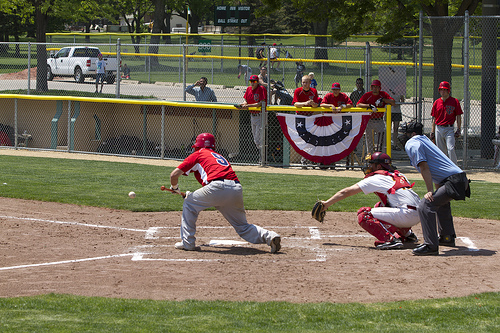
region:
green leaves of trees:
[0, 1, 482, 31]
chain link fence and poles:
[2, 11, 498, 167]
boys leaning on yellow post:
[240, 71, 390, 111]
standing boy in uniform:
[428, 78, 464, 155]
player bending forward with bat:
[163, 132, 285, 251]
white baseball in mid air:
[123, 187, 143, 204]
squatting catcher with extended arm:
[310, 151, 415, 248]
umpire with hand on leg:
[397, 120, 468, 257]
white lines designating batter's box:
[129, 222, 328, 262]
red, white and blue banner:
[276, 109, 375, 166]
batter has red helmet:
[190, 119, 210, 154]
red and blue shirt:
[183, 144, 250, 186]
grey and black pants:
[172, 181, 274, 241]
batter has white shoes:
[252, 222, 277, 263]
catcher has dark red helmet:
[355, 147, 396, 173]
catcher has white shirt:
[337, 177, 452, 223]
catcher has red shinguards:
[357, 205, 422, 255]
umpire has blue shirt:
[401, 130, 468, 192]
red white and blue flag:
[281, 110, 378, 170]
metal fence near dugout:
[15, 32, 335, 177]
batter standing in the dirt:
[133, 123, 296, 258]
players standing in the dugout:
[234, 67, 404, 171]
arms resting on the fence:
[289, 93, 316, 113]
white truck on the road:
[30, 41, 130, 85]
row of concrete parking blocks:
[117, 73, 232, 92]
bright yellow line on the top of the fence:
[3, 86, 394, 131]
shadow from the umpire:
[444, 239, 490, 259]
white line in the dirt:
[3, 241, 131, 278]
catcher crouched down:
[307, 141, 421, 258]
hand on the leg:
[422, 186, 436, 203]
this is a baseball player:
[161, 125, 262, 255]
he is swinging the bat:
[156, 127, 249, 250]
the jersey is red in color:
[186, 147, 231, 182]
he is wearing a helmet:
[193, 132, 215, 146]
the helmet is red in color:
[195, 135, 213, 146]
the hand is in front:
[310, 182, 357, 224]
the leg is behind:
[231, 210, 285, 254]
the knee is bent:
[228, 216, 260, 240]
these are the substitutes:
[294, 73, 391, 108]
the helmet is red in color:
[434, 79, 451, 88]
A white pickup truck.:
[42, 45, 122, 80]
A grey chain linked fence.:
[0, 10, 497, 171]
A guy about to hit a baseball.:
[125, 130, 280, 255]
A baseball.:
[125, 190, 135, 195]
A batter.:
[160, 131, 282, 252]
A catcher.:
[314, 152, 421, 252]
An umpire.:
[394, 120, 476, 257]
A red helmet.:
[190, 130, 217, 150]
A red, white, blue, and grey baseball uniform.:
[172, 147, 275, 242]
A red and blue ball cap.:
[331, 82, 342, 93]